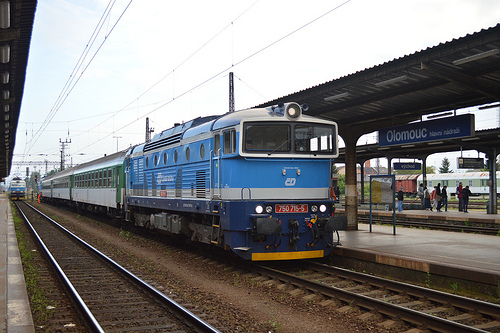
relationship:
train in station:
[34, 99, 348, 259] [0, 0, 498, 331]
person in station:
[391, 187, 407, 213] [0, 0, 498, 331]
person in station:
[455, 181, 465, 211] [0, 0, 498, 331]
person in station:
[461, 179, 472, 210] [0, 0, 498, 331]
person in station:
[439, 183, 452, 214] [0, 0, 498, 331]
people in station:
[406, 175, 481, 215] [0, 0, 498, 331]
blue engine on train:
[123, 101, 338, 266] [34, 99, 348, 259]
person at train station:
[435, 181, 453, 214] [267, 57, 498, 285]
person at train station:
[392, 183, 406, 213] [267, 57, 498, 285]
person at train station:
[429, 181, 445, 212] [267, 57, 498, 285]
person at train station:
[456, 179, 466, 208] [267, 57, 498, 285]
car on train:
[71, 143, 132, 220] [34, 99, 348, 259]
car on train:
[175, 112, 326, 242] [34, 99, 348, 259]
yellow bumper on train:
[248, 246, 326, 263] [35, 99, 372, 264]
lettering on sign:
[380, 123, 460, 138] [366, 103, 493, 164]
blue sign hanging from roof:
[373, 112, 476, 151] [272, 30, 498, 135]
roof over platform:
[272, 30, 498, 135] [330, 220, 497, 275]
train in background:
[3, 172, 30, 197] [5, 158, 53, 226]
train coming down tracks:
[3, 172, 30, 197] [10, 199, 247, 331]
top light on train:
[277, 98, 310, 123] [34, 99, 348, 259]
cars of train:
[41, 144, 131, 213] [35, 172, 149, 218]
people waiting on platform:
[415, 180, 474, 216] [285, 188, 498, 298]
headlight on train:
[243, 202, 278, 217] [39, 99, 337, 270]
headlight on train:
[319, 204, 326, 211] [34, 99, 348, 259]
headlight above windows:
[285, 101, 302, 118] [243, 118, 337, 167]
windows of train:
[243, 118, 337, 167] [126, 101, 341, 267]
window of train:
[291, 122, 337, 157] [39, 99, 337, 270]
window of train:
[241, 117, 292, 155] [39, 99, 337, 270]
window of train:
[185, 145, 191, 162] [39, 99, 337, 270]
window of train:
[198, 143, 206, 159] [39, 99, 337, 270]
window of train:
[142, 155, 151, 170] [39, 99, 337, 270]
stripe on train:
[245, 240, 335, 262] [34, 99, 348, 259]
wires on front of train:
[254, 213, 329, 250] [28, 104, 343, 276]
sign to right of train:
[372, 112, 477, 149] [28, 104, 343, 276]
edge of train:
[206, 188, 268, 246] [39, 99, 337, 270]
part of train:
[204, 221, 223, 249] [30, 71, 453, 289]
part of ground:
[177, 261, 234, 304] [36, 202, 376, 330]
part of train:
[251, 161, 294, 204] [34, 99, 348, 259]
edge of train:
[214, 132, 254, 196] [211, 114, 300, 222]